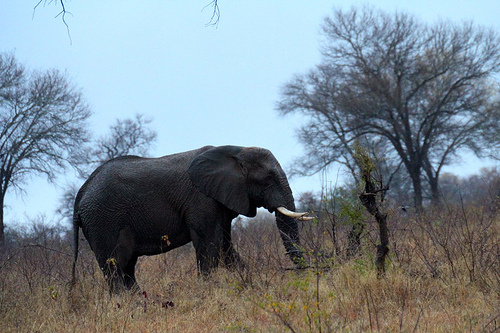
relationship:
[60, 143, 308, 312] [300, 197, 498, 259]
elephant in brush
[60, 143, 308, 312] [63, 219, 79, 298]
elephant has tail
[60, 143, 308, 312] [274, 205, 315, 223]
elephant has tusks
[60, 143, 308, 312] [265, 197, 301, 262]
elephant has trunk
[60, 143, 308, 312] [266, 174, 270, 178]
elephant has eye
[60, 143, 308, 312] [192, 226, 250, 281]
elephant has legs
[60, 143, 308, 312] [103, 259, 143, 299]
elephant has legs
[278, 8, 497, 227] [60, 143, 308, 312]
trees behind elephant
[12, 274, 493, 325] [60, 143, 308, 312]
grass under elephant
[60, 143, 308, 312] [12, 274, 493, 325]
elephant in grass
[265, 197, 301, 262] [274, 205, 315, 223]
trunk between tusks